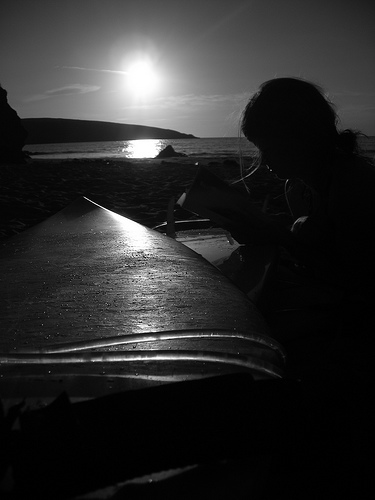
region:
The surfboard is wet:
[3, 185, 278, 410]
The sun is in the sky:
[109, 45, 172, 110]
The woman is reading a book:
[182, 70, 373, 284]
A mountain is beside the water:
[24, 109, 208, 144]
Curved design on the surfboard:
[18, 312, 295, 403]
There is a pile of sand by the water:
[143, 136, 191, 169]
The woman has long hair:
[228, 56, 374, 168]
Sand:
[92, 166, 209, 250]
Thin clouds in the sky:
[181, 74, 223, 126]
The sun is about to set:
[64, 23, 200, 171]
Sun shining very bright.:
[110, 47, 177, 115]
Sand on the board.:
[62, 242, 169, 329]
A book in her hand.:
[175, 161, 270, 238]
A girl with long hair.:
[210, 53, 365, 184]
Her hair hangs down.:
[225, 108, 265, 201]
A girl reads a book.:
[171, 16, 372, 258]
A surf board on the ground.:
[9, 175, 278, 439]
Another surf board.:
[147, 195, 237, 268]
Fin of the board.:
[158, 200, 180, 235]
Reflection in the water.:
[120, 138, 162, 159]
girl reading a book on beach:
[173, 101, 355, 279]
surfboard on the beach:
[14, 190, 279, 376]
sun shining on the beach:
[107, 38, 186, 167]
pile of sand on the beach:
[153, 144, 202, 179]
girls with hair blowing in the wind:
[224, 67, 372, 203]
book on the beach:
[164, 168, 274, 253]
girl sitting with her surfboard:
[25, 61, 348, 356]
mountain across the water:
[42, 105, 174, 135]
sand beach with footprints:
[55, 161, 138, 192]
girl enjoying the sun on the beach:
[151, 45, 364, 330]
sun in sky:
[109, 46, 173, 109]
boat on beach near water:
[18, 193, 281, 401]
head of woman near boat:
[233, 72, 361, 190]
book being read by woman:
[178, 160, 280, 251]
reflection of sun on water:
[120, 133, 165, 163]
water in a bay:
[18, 132, 258, 163]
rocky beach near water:
[38, 155, 182, 212]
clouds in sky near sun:
[31, 61, 117, 110]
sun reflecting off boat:
[92, 204, 163, 265]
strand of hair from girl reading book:
[222, 125, 264, 189]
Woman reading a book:
[171, 67, 338, 272]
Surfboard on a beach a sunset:
[19, 176, 296, 438]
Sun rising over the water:
[109, 56, 188, 138]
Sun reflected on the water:
[116, 125, 168, 164]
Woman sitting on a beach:
[227, 72, 352, 286]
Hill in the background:
[21, 106, 167, 148]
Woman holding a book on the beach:
[181, 81, 364, 326]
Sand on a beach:
[48, 161, 125, 185]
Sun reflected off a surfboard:
[96, 206, 171, 276]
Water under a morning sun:
[78, 137, 139, 163]